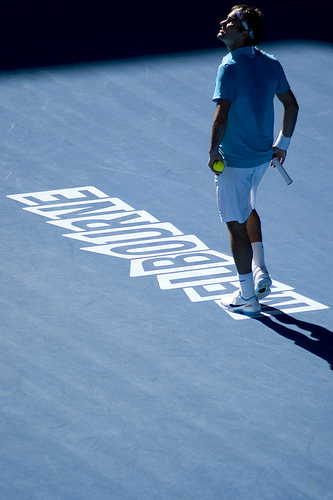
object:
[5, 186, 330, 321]
letters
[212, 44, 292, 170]
shirt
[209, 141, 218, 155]
wrist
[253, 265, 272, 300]
shoe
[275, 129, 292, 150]
band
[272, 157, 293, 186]
handle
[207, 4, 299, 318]
man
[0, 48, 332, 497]
floor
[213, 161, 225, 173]
ball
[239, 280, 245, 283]
sock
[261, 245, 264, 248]
sock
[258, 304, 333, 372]
shadow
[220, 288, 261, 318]
shoe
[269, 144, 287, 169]
hand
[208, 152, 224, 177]
hand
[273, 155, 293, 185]
grip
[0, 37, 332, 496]
tarp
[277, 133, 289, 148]
wrist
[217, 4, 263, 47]
head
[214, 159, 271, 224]
shorts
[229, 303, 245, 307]
swoosh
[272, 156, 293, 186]
racket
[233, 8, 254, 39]
headband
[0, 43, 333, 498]
court